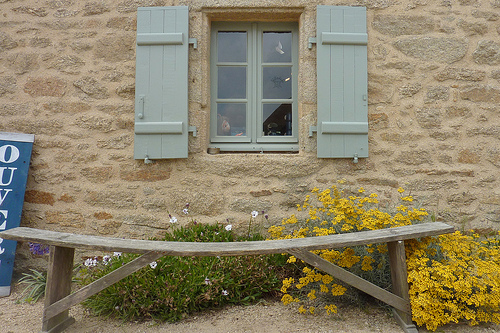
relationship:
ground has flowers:
[1, 278, 499, 331] [407, 231, 498, 331]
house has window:
[3, 2, 497, 282] [211, 20, 299, 151]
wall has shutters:
[2, 0, 498, 278] [314, 5, 371, 158]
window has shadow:
[211, 20, 299, 151] [264, 99, 293, 135]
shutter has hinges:
[133, 6, 191, 160] [188, 36, 198, 139]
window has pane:
[211, 20, 299, 151] [218, 30, 246, 60]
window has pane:
[211, 20, 299, 151] [263, 32, 292, 62]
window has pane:
[211, 20, 299, 151] [217, 65, 245, 97]